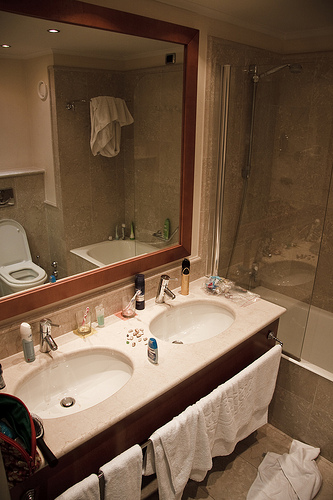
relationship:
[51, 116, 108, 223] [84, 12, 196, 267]
wall in mirror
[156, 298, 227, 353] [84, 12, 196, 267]
sink in mirror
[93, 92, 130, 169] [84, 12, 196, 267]
towel in mirror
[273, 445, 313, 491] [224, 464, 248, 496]
towel on floor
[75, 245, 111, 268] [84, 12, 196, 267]
tub in mirror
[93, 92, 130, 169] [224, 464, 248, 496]
towel on floor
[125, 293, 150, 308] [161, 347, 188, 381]
brush on counter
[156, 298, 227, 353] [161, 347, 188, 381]
sink on counter